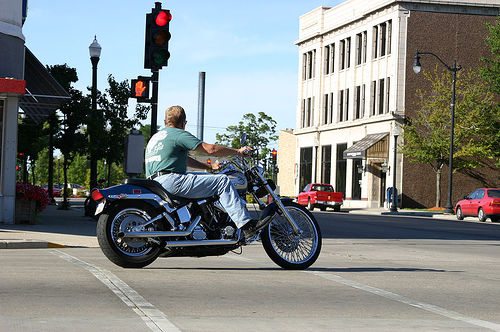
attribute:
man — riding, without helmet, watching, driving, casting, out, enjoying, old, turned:
[153, 95, 232, 196]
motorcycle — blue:
[102, 175, 324, 260]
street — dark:
[357, 219, 447, 277]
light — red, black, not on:
[132, 13, 195, 71]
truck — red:
[297, 175, 335, 211]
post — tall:
[70, 41, 115, 179]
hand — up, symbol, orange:
[133, 82, 156, 105]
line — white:
[124, 286, 150, 312]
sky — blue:
[179, 16, 247, 66]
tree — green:
[60, 143, 80, 174]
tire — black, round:
[255, 202, 324, 264]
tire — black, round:
[81, 186, 167, 272]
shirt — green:
[150, 124, 193, 170]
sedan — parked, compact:
[455, 187, 499, 223]